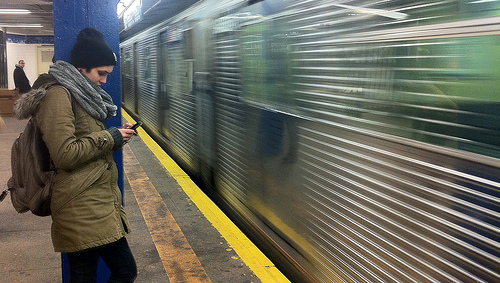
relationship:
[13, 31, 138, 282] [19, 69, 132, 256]
person has jacket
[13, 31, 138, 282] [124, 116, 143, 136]
person has phone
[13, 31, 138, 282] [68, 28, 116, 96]
person has head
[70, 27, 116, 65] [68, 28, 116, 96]
hat on head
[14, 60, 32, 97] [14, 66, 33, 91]
man has jacket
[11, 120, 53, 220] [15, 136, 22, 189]
backpack has zipper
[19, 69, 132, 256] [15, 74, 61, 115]
jacket has hood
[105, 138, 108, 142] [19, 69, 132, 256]
button on jacket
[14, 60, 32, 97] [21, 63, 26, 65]
man wears glasses